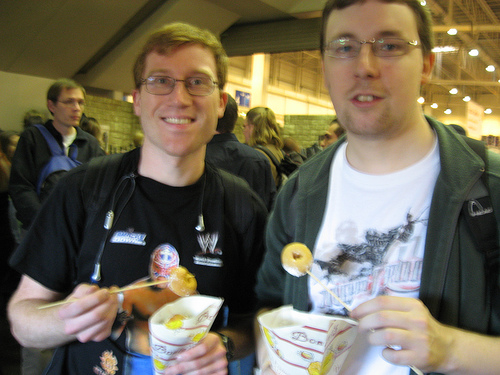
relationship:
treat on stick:
[271, 221, 336, 281] [300, 259, 430, 370]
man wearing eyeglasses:
[249, 0, 484, 372] [327, 28, 422, 58]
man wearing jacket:
[249, 0, 484, 372] [250, 113, 498, 372]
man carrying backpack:
[10, 77, 106, 238] [36, 120, 92, 175]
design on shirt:
[316, 213, 416, 281] [311, 140, 443, 373]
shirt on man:
[311, 140, 443, 373] [249, 0, 484, 372]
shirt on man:
[311, 140, 443, 373] [258, 3, 498, 373]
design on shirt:
[309, 210, 433, 302] [311, 140, 443, 373]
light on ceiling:
[412, 88, 428, 111] [418, 3, 483, 110]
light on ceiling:
[429, 93, 446, 125] [423, 2, 482, 128]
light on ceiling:
[439, 102, 457, 114] [429, 2, 479, 102]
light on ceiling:
[423, 7, 430, 9] [414, 1, 484, 135]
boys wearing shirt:
[7, 21, 265, 375] [10, 137, 297, 370]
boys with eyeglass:
[7, 21, 265, 375] [136, 72, 222, 96]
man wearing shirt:
[249, 0, 484, 372] [329, 136, 426, 372]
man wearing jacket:
[249, 0, 484, 372] [267, 111, 481, 347]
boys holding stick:
[7, 21, 265, 375] [299, 263, 410, 373]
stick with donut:
[299, 263, 410, 373] [273, 235, 321, 277]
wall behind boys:
[83, 98, 147, 153] [7, 21, 265, 375]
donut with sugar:
[160, 260, 205, 297] [162, 276, 179, 291]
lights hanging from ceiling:
[429, 37, 484, 134] [428, 2, 483, 112]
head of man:
[35, 71, 88, 133] [9, 71, 111, 234]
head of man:
[116, 18, 233, 165] [2, 18, 254, 372]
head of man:
[313, 2, 476, 146] [249, 0, 484, 372]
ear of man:
[42, 93, 58, 118] [11, 76, 118, 239]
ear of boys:
[117, 83, 144, 121] [7, 21, 265, 375]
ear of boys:
[212, 81, 239, 122] [7, 21, 265, 375]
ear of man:
[414, 43, 444, 93] [253, 4, 483, 339]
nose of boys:
[162, 76, 193, 108] [7, 21, 265, 375]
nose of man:
[342, 40, 386, 90] [249, 0, 484, 372]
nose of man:
[61, 95, 84, 115] [2, 60, 113, 227]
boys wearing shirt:
[7, 21, 265, 375] [10, 150, 264, 375]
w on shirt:
[192, 230, 223, 253] [12, 140, 271, 368]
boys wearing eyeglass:
[7, 21, 265, 375] [124, 59, 234, 94]